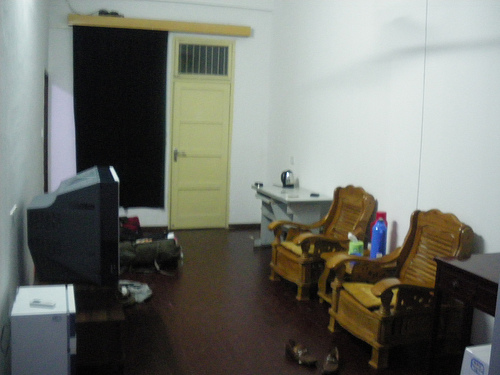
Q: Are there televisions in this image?
A: Yes, there is a television.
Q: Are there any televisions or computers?
A: Yes, there is a television.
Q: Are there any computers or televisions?
A: Yes, there is a television.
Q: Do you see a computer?
A: No, there are no computers.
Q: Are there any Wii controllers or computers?
A: No, there are no computers or Wii controllers.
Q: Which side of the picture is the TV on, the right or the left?
A: The TV is on the left of the image.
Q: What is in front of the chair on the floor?
A: The TV is in front of the chair.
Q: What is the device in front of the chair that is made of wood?
A: The device is a television.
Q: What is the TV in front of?
A: The TV is in front of the chair.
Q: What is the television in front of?
A: The TV is in front of the chair.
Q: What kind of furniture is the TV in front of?
A: The TV is in front of the chair.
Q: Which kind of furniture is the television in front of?
A: The TV is in front of the chair.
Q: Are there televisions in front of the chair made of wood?
A: Yes, there is a television in front of the chair.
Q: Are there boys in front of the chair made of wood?
A: No, there is a television in front of the chair.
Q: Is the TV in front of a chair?
A: Yes, the TV is in front of a chair.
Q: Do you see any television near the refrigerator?
A: Yes, there is a television near the refrigerator.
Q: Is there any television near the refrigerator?
A: Yes, there is a television near the refrigerator.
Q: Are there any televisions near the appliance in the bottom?
A: Yes, there is a television near the refrigerator.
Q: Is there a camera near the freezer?
A: No, there is a television near the freezer.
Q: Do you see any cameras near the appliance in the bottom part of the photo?
A: No, there is a television near the freezer.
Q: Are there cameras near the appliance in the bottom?
A: No, there is a television near the freezer.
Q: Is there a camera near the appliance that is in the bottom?
A: No, there is a television near the freezer.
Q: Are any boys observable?
A: No, there are no boys.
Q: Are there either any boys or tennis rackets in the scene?
A: No, there are no boys or tennis rackets.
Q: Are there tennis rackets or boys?
A: No, there are no boys or tennis rackets.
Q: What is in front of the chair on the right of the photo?
A: The shoe is in front of the chair.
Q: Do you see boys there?
A: No, there are no boys.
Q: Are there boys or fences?
A: No, there are no boys or fences.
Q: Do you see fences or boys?
A: No, there are no boys or fences.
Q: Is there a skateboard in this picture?
A: No, there are no skateboards.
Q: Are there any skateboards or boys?
A: No, there are no skateboards or boys.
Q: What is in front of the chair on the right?
A: The shoe is in front of the chair.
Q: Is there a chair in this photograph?
A: Yes, there is a chair.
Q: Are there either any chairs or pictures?
A: Yes, there is a chair.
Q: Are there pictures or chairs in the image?
A: Yes, there is a chair.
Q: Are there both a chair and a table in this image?
A: Yes, there are both a chair and a table.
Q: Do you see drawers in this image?
A: No, there are no drawers.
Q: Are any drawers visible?
A: No, there are no drawers.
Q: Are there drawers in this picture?
A: No, there are no drawers.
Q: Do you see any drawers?
A: No, there are no drawers.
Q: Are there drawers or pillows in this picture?
A: No, there are no drawers or pillows.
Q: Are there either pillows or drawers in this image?
A: No, there are no drawers or pillows.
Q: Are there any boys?
A: No, there are no boys.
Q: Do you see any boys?
A: No, there are no boys.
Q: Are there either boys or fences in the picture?
A: No, there are no boys or fences.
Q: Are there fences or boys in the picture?
A: No, there are no boys or fences.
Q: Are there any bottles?
A: Yes, there is a bottle.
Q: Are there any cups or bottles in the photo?
A: Yes, there is a bottle.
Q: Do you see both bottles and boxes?
A: Yes, there are both a bottle and a box.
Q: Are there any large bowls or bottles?
A: Yes, there is a large bottle.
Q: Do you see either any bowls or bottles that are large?
A: Yes, the bottle is large.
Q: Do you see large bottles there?
A: Yes, there is a large bottle.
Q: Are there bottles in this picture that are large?
A: Yes, there is a bottle that is large.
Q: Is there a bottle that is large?
A: Yes, there is a bottle that is large.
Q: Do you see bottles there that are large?
A: Yes, there is a bottle that is large.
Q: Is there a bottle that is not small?
A: Yes, there is a large bottle.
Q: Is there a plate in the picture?
A: No, there are no plates.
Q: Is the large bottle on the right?
A: Yes, the bottle is on the right of the image.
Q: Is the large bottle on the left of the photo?
A: No, the bottle is on the right of the image.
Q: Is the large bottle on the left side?
A: No, the bottle is on the right of the image.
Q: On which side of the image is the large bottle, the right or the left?
A: The bottle is on the right of the image.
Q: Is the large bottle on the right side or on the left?
A: The bottle is on the right of the image.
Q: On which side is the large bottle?
A: The bottle is on the right of the image.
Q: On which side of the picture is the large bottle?
A: The bottle is on the right of the image.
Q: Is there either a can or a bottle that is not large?
A: No, there is a bottle but it is large.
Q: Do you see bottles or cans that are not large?
A: No, there is a bottle but it is large.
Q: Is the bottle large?
A: Yes, the bottle is large.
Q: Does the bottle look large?
A: Yes, the bottle is large.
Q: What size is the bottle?
A: The bottle is large.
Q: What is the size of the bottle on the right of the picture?
A: The bottle is large.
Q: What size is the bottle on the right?
A: The bottle is large.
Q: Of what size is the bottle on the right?
A: The bottle is large.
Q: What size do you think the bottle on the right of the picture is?
A: The bottle is large.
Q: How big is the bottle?
A: The bottle is large.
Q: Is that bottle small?
A: No, the bottle is large.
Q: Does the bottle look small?
A: No, the bottle is large.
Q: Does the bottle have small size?
A: No, the bottle is large.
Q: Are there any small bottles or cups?
A: No, there is a bottle but it is large.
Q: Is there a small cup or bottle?
A: No, there is a bottle but it is large.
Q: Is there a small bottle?
A: No, there is a bottle but it is large.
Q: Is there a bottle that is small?
A: No, there is a bottle but it is large.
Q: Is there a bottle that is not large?
A: No, there is a bottle but it is large.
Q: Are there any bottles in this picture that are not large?
A: No, there is a bottle but it is large.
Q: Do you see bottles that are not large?
A: No, there is a bottle but it is large.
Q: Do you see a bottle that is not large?
A: No, there is a bottle but it is large.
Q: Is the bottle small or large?
A: The bottle is large.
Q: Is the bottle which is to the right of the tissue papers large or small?
A: The bottle is large.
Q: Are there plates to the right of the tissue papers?
A: No, there is a bottle to the right of the tissue papers.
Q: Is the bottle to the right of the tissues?
A: Yes, the bottle is to the right of the tissues.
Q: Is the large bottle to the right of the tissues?
A: Yes, the bottle is to the right of the tissues.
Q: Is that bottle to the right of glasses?
A: No, the bottle is to the right of the tissues.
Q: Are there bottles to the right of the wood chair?
A: Yes, there is a bottle to the right of the chair.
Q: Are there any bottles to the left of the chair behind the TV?
A: No, the bottle is to the right of the chair.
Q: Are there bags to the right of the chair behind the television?
A: No, there is a bottle to the right of the chair.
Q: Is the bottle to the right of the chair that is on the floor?
A: Yes, the bottle is to the right of the chair.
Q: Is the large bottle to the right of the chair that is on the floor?
A: Yes, the bottle is to the right of the chair.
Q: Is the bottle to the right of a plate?
A: No, the bottle is to the right of the chair.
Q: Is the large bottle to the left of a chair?
A: No, the bottle is to the right of a chair.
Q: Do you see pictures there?
A: No, there are no pictures.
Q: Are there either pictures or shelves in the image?
A: No, there are no pictures or shelves.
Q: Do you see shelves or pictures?
A: No, there are no pictures or shelves.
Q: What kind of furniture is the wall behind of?
A: The wall is behind the desk.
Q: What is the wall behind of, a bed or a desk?
A: The wall is behind a desk.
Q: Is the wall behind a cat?
A: No, the wall is behind a desk.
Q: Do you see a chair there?
A: Yes, there is a chair.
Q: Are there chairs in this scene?
A: Yes, there is a chair.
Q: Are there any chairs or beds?
A: Yes, there is a chair.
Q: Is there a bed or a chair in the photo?
A: Yes, there is a chair.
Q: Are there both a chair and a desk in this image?
A: Yes, there are both a chair and a desk.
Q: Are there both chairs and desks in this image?
A: Yes, there are both a chair and a desk.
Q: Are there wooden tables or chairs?
A: Yes, there is a wood chair.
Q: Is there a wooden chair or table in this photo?
A: Yes, there is a wood chair.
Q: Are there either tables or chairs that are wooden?
A: Yes, the chair is wooden.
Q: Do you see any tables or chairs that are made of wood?
A: Yes, the chair is made of wood.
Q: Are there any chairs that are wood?
A: Yes, there is a wood chair.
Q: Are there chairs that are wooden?
A: Yes, there is a chair that is wooden.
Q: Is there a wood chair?
A: Yes, there is a chair that is made of wood.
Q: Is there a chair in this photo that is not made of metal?
A: Yes, there is a chair that is made of wood.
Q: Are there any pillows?
A: No, there are no pillows.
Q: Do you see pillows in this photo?
A: No, there are no pillows.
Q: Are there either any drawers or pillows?
A: No, there are no pillows or drawers.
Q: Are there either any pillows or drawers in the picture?
A: No, there are no pillows or drawers.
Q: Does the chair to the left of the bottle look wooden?
A: Yes, the chair is wooden.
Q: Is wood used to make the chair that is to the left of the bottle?
A: Yes, the chair is made of wood.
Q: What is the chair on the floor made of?
A: The chair is made of wood.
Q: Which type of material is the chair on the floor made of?
A: The chair is made of wood.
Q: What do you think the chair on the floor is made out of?
A: The chair is made of wood.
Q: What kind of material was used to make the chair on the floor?
A: The chair is made of wood.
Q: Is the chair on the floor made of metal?
A: No, the chair is made of wood.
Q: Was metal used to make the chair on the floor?
A: No, the chair is made of wood.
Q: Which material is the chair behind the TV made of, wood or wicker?
A: The chair is made of wood.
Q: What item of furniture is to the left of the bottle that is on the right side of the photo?
A: The piece of furniture is a chair.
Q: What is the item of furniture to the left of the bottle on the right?
A: The piece of furniture is a chair.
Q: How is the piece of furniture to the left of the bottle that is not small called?
A: The piece of furniture is a chair.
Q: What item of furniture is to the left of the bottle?
A: The piece of furniture is a chair.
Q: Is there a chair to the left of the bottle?
A: Yes, there is a chair to the left of the bottle.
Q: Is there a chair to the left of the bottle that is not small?
A: Yes, there is a chair to the left of the bottle.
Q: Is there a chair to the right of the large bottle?
A: No, the chair is to the left of the bottle.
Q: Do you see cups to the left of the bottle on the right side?
A: No, there is a chair to the left of the bottle.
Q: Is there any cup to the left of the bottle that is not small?
A: No, there is a chair to the left of the bottle.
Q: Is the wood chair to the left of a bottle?
A: Yes, the chair is to the left of a bottle.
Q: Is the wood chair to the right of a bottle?
A: No, the chair is to the left of a bottle.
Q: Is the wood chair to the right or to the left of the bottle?
A: The chair is to the left of the bottle.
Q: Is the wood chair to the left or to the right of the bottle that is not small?
A: The chair is to the left of the bottle.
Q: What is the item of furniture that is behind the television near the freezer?
A: The piece of furniture is a chair.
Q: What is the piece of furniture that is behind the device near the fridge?
A: The piece of furniture is a chair.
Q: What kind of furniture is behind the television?
A: The piece of furniture is a chair.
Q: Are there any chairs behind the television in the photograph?
A: Yes, there is a chair behind the television.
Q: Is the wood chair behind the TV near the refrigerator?
A: Yes, the chair is behind the TV.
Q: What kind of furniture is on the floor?
A: The piece of furniture is a chair.